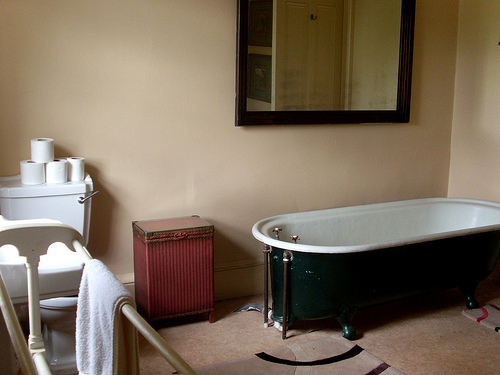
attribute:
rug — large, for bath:
[176, 329, 404, 372]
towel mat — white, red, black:
[458, 296, 498, 336]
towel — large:
[78, 254, 135, 371]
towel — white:
[64, 243, 176, 344]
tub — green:
[240, 185, 498, 332]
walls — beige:
[3, 10, 441, 275]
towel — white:
[73, 262, 133, 373]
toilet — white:
[2, 172, 98, 368]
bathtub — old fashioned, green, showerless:
[261, 190, 493, 338]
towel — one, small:
[466, 298, 498, 330]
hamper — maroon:
[122, 212, 223, 341]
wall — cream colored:
[158, 114, 380, 219]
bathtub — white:
[255, 196, 499, 323]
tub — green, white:
[227, 189, 454, 339]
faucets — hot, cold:
[270, 224, 300, 246]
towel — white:
[69, 254, 148, 374]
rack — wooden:
[0, 222, 196, 374]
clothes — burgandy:
[43, 205, 138, 350]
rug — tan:
[198, 327, 403, 371]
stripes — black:
[257, 342, 391, 369]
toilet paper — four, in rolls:
[18, 134, 84, 184]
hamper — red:
[132, 213, 218, 330]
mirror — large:
[238, 0, 404, 115]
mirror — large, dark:
[234, 1, 415, 127]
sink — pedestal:
[1, 216, 93, 305]